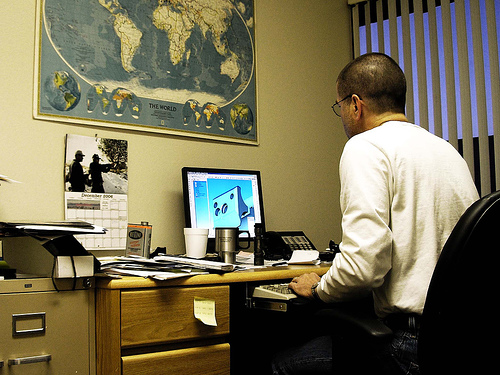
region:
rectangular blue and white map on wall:
[29, 1, 266, 148]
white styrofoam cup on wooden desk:
[178, 223, 211, 267]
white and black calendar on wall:
[56, 131, 135, 258]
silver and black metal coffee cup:
[212, 224, 252, 266]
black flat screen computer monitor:
[178, 166, 272, 261]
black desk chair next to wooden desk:
[308, 178, 498, 373]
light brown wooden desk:
[61, 246, 481, 373]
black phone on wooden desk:
[256, 228, 322, 263]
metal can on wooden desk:
[123, 218, 155, 267]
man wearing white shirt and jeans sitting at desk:
[248, 50, 485, 373]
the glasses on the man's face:
[330, 91, 362, 117]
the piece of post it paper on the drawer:
[192, 295, 217, 327]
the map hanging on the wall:
[32, 0, 260, 146]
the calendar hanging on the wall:
[61, 133, 128, 251]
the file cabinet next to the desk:
[0, 277, 96, 374]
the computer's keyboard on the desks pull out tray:
[250, 279, 297, 300]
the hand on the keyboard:
[287, 271, 320, 295]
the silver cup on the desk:
[214, 227, 249, 264]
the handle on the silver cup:
[236, 229, 250, 251]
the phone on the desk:
[265, 230, 319, 261]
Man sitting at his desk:
[316, 121, 480, 314]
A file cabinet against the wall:
[0, 280, 97, 373]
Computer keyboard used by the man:
[253, 280, 310, 300]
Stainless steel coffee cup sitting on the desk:
[213, 229, 251, 262]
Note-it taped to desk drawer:
[192, 295, 216, 327]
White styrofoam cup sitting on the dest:
[181, 227, 209, 256]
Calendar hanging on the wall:
[63, 136, 129, 251]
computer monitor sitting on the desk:
[181, 167, 266, 252]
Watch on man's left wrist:
[309, 277, 320, 297]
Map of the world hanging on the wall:
[32, 2, 258, 146]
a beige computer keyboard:
[253, 280, 296, 300]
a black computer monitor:
[179, 164, 266, 253]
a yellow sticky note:
[191, 295, 218, 329]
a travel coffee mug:
[214, 225, 251, 265]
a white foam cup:
[181, 226, 209, 260]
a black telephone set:
[261, 228, 318, 262]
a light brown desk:
[94, 262, 329, 373]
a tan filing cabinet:
[0, 275, 95, 372]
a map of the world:
[31, 0, 256, 147]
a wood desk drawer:
[118, 284, 231, 350]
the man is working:
[146, 50, 438, 365]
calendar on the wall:
[46, 103, 174, 265]